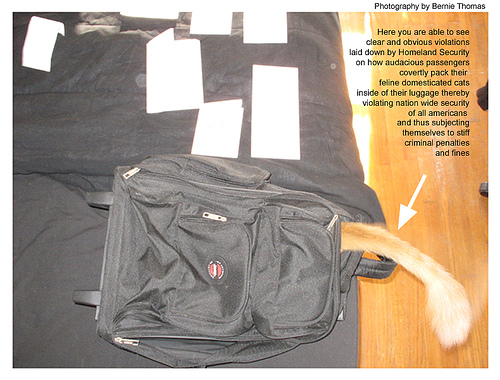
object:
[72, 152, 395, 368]
suitcase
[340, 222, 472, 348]
tail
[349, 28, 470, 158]
text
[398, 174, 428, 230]
arrow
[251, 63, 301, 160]
envelope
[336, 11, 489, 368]
floor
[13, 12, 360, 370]
bed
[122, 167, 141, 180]
zipper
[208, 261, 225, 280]
logo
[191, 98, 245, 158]
papers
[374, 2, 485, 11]
credit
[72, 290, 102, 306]
foot